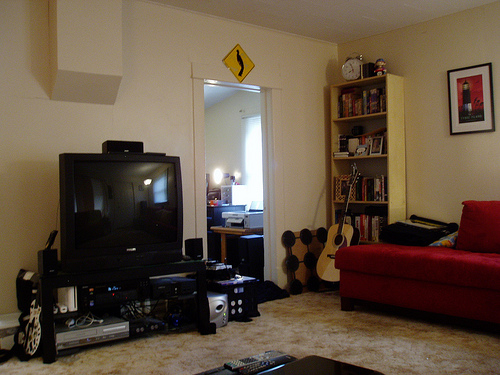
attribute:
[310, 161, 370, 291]
guitar — wooden, acoustic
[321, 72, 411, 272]
bookshelf — four layer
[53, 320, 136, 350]
set — dvd player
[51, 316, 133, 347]
player — silver, plastic, video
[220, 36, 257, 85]
sign — yellow, black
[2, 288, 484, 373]
carpet — beige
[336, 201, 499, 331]
couch — red sofa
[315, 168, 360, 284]
guitar — beside couch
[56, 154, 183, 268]
television — on the stand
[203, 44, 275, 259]
above the door — sign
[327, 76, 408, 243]
bookshelf — against the wall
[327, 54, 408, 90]
top of bookshelf — large clock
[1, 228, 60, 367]
electric guitar — electric guitar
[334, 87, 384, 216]
books — on the shelf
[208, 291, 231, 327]
stereo speaker — silver, down on the ground